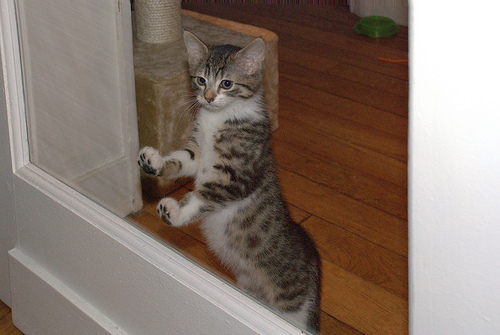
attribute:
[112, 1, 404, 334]
floor — in house, wooden, brown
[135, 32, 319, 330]
cat — furry, gray, black, white, tabby, standing, grey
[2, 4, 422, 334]
door — covering house, white, wooden, glass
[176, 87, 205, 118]
whiskers — white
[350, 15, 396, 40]
bowl — inside house, green, small, for water, plastic, nearly full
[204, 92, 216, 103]
nose — light, light brown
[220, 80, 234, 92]
left eye — soft blue, open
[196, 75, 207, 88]
right eye — blue, open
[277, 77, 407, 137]
slat — wooden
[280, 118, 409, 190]
slat — brown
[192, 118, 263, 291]
underbelly — white, furry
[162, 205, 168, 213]
pad — black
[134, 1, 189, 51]
scratching pad — brown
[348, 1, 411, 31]
wall — white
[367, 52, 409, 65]
object — orange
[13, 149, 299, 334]
base — white